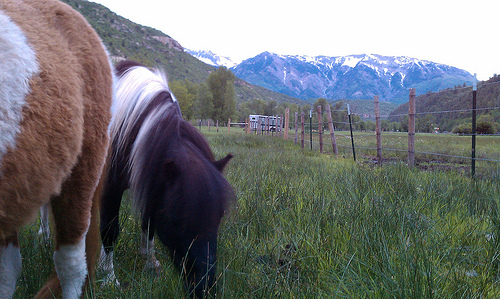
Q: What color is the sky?
A: White.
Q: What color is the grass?
A: Green.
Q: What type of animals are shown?
A: Ponies.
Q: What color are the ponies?
A: Black and brown and white.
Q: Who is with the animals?
A: No one.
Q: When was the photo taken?
A: Afternoon.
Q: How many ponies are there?
A: Two.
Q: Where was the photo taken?
A: In a field.